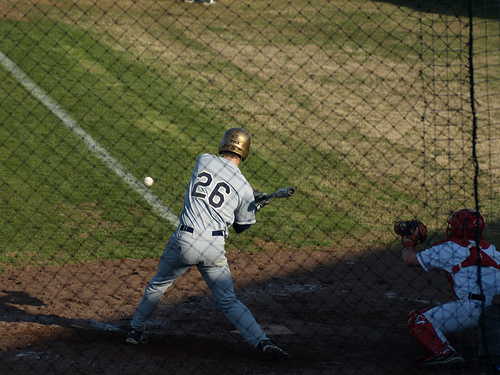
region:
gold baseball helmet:
[218, 127, 255, 160]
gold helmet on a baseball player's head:
[216, 126, 253, 160]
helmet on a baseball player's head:
[217, 125, 253, 160]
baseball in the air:
[140, 173, 154, 186]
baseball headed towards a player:
[113, 128, 298, 373]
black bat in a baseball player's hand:
[248, 183, 295, 203]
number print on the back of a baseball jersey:
[189, 169, 234, 209]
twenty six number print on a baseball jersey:
[187, 171, 232, 208]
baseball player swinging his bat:
[123, 124, 302, 366]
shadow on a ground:
[0, 284, 133, 336]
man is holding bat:
[140, 124, 305, 341]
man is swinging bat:
[248, 180, 300, 209]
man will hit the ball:
[239, 176, 296, 223]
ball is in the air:
[134, 173, 156, 193]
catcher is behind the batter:
[395, 207, 499, 348]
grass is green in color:
[34, 73, 159, 138]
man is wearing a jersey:
[162, 124, 264, 274]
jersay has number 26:
[182, 150, 253, 235]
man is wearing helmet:
[174, 127, 288, 300]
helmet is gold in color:
[217, 125, 255, 168]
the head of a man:
[183, 125, 261, 176]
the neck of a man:
[207, 142, 250, 179]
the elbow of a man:
[223, 214, 263, 234]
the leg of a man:
[107, 243, 207, 346]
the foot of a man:
[111, 314, 173, 354]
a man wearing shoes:
[114, 275, 382, 359]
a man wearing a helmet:
[141, 88, 287, 257]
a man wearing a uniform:
[108, 118, 327, 353]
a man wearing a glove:
[366, 210, 497, 313]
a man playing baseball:
[116, 114, 353, 356]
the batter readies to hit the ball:
[117, 120, 302, 365]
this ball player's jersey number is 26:
[184, 165, 239, 210]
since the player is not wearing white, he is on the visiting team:
[119, 150, 302, 366]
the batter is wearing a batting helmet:
[214, 123, 253, 163]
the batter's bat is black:
[254, 185, 296, 203]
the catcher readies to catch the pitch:
[388, 203, 499, 373]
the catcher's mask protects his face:
[440, 205, 488, 246]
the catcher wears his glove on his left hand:
[389, 214, 432, 251]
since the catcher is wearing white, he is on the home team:
[409, 232, 499, 362]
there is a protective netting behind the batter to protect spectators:
[3, 2, 495, 372]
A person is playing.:
[122, 134, 287, 358]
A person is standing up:
[109, 112, 294, 371]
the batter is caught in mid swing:
[126, 125, 301, 368]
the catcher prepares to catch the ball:
[383, 202, 496, 373]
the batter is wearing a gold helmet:
[218, 124, 254, 161]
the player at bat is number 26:
[191, 169, 230, 209]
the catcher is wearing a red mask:
[442, 206, 487, 248]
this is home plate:
[231, 315, 289, 341]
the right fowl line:
[3, 53, 188, 223]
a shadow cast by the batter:
[1, 284, 111, 337]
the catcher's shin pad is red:
[397, 311, 452, 363]